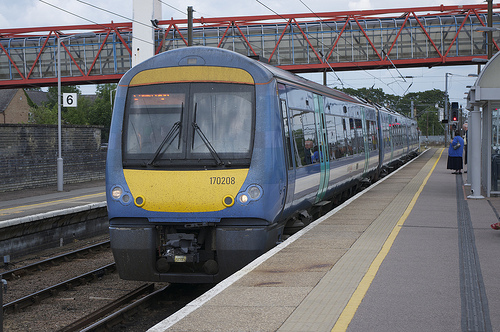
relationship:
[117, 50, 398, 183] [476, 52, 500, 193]
train at train station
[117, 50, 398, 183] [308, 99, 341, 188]
train has double doors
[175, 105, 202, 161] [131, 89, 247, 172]
windshield wipers on windshield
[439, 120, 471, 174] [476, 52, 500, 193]
woman at train station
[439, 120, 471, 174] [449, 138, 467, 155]
woman in blue shirt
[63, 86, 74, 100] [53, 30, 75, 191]
number 6 on pole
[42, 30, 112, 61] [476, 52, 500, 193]
lights at train station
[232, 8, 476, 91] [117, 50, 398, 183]
bridge over train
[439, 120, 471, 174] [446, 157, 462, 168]
woman in black skirt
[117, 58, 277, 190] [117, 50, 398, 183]
front of train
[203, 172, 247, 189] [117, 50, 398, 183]
number on train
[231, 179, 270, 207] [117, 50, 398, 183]
headlight on train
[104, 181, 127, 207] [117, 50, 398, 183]
headlight on train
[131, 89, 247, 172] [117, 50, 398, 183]
windshield on train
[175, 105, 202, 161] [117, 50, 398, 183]
windshield wipers on train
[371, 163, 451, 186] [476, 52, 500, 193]
lines at train station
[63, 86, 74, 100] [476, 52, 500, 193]
number 6 at train station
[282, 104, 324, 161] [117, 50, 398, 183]
windows on train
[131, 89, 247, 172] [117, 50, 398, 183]
windshield of train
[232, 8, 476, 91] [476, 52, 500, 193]
bridge over train station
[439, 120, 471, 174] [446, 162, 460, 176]
woman in black skirt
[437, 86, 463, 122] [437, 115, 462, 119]
stoplight has red light